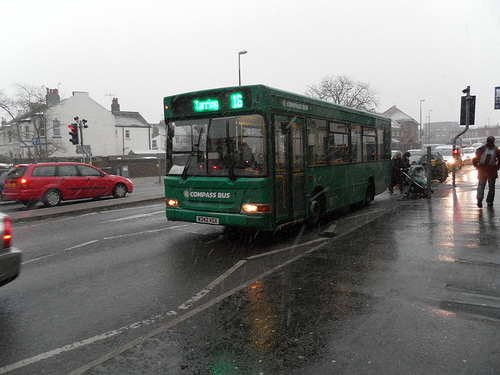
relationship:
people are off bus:
[392, 150, 436, 204] [384, 140, 437, 203]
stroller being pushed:
[390, 154, 434, 202] [392, 150, 436, 204]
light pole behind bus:
[229, 44, 257, 85] [384, 140, 437, 203]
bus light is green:
[384, 140, 437, 203] [189, 90, 245, 115]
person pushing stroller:
[392, 150, 436, 204] [402, 160, 429, 200]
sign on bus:
[191, 85, 246, 115] [181, 82, 250, 120]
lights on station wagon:
[7, 159, 27, 184] [1, 160, 137, 207]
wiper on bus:
[209, 120, 247, 179] [155, 75, 405, 245]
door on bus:
[266, 110, 309, 223] [154, 82, 392, 236]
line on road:
[203, 241, 333, 279] [2, 167, 497, 373]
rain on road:
[68, 236, 307, 349] [2, 167, 497, 373]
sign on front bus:
[167, 162, 187, 180] [160, 78, 410, 228]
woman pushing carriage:
[394, 144, 414, 202] [392, 150, 436, 204]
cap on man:
[391, 150, 404, 165] [474, 131, 497, 211]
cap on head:
[391, 150, 404, 165] [485, 133, 496, 148]